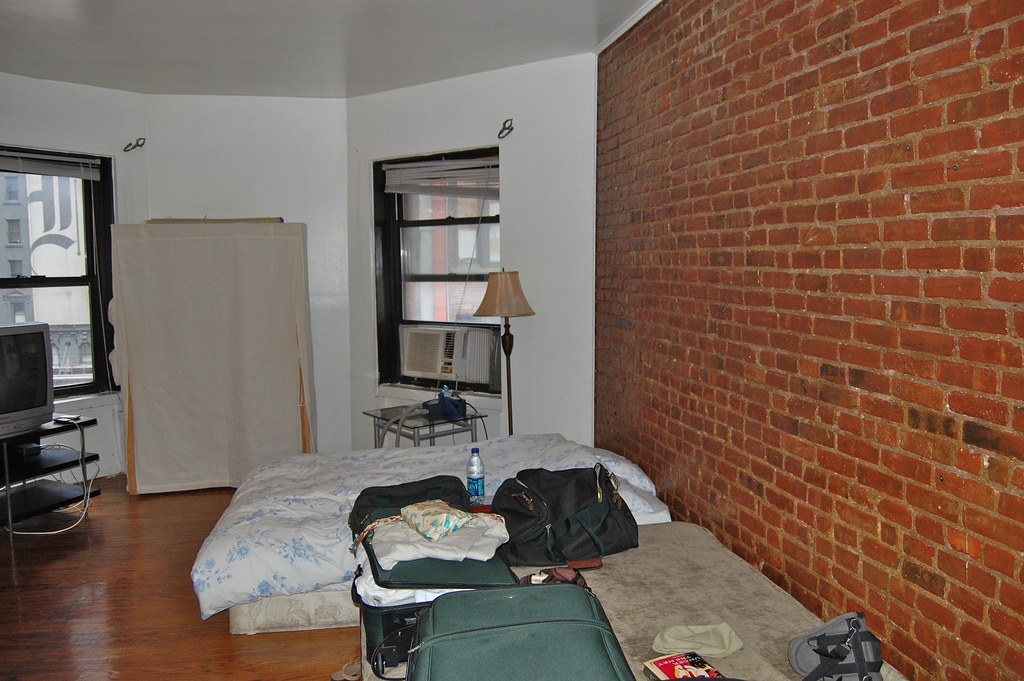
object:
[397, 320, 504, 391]
air conditioner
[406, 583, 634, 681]
luggage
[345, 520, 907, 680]
bed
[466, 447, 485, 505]
water bottle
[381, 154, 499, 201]
blind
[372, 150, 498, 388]
window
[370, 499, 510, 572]
clothes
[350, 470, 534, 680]
luggage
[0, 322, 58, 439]
tv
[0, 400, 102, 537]
stand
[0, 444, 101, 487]
shelf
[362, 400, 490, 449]
table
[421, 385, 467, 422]
phone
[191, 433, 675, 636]
bed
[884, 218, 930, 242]
brick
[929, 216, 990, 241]
brick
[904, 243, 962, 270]
brick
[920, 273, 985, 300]
brick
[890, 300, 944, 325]
brick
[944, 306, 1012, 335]
brick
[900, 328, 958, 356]
brick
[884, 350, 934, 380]
brick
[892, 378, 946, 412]
brick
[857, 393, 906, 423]
brick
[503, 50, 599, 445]
wall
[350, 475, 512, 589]
clothes laying